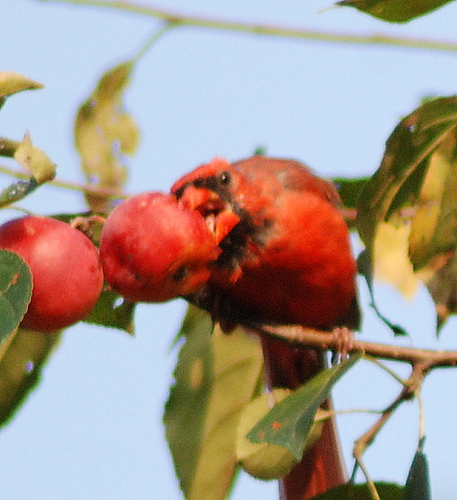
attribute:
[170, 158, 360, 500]
bird — robin, in picture, red, black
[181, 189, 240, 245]
beak — red, open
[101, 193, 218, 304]
fruit — red, in picture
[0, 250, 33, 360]
leaf — green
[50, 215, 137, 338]
leaf — green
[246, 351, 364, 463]
leaf — torn, green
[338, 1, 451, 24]
leaf — green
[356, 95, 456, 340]
leaf — green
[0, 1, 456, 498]
sky — clear, blue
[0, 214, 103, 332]
fruit — red, in picture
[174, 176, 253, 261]
marking — black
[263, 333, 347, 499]
tail feathers — red, long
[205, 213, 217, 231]
tongue — pink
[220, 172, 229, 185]
eye — black